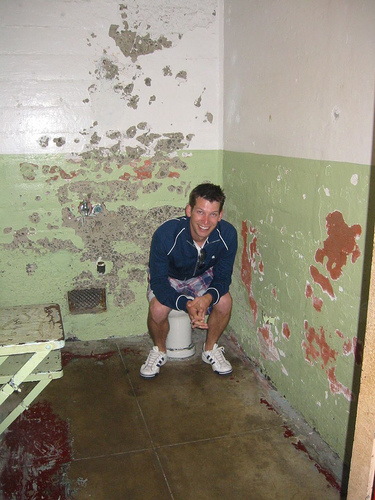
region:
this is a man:
[130, 181, 241, 379]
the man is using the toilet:
[127, 183, 257, 367]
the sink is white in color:
[169, 312, 188, 360]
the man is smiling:
[199, 224, 208, 229]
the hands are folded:
[184, 291, 210, 329]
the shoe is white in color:
[199, 344, 232, 377]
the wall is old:
[0, 0, 160, 220]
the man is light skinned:
[205, 205, 212, 210]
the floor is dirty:
[43, 398, 262, 499]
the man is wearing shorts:
[182, 282, 201, 291]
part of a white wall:
[295, 29, 345, 86]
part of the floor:
[187, 439, 233, 481]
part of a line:
[146, 455, 170, 486]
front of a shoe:
[134, 368, 155, 381]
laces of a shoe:
[214, 348, 226, 362]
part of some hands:
[185, 301, 211, 331]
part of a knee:
[152, 298, 163, 332]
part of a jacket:
[170, 246, 190, 269]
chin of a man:
[194, 220, 205, 242]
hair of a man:
[201, 188, 224, 205]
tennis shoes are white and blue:
[190, 328, 238, 396]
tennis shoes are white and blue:
[129, 328, 168, 392]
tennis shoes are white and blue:
[195, 339, 230, 378]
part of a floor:
[186, 413, 233, 452]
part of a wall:
[112, 303, 129, 326]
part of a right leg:
[151, 326, 169, 345]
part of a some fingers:
[191, 312, 201, 331]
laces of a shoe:
[212, 344, 222, 359]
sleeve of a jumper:
[168, 295, 185, 302]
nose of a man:
[200, 214, 211, 228]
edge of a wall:
[297, 408, 317, 436]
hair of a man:
[196, 182, 221, 200]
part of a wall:
[268, 88, 322, 130]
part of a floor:
[177, 445, 228, 491]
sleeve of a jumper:
[178, 296, 186, 311]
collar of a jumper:
[179, 233, 194, 250]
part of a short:
[189, 278, 204, 291]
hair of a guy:
[196, 184, 223, 202]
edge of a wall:
[301, 412, 329, 450]